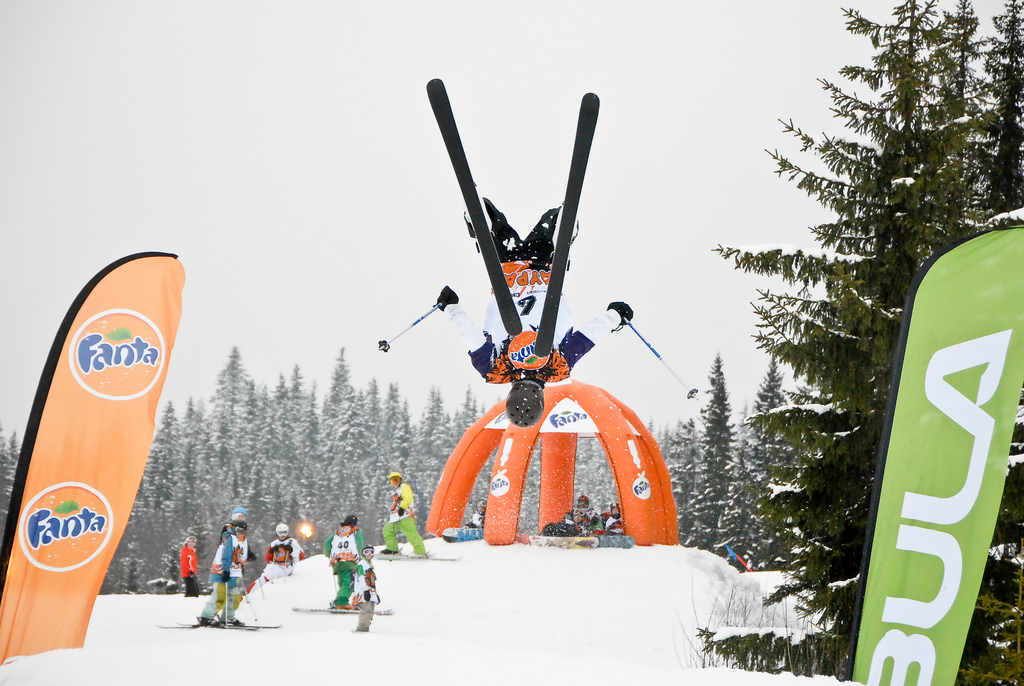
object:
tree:
[681, 350, 739, 551]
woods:
[2, 0, 1023, 685]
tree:
[647, 415, 679, 476]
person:
[378, 472, 432, 560]